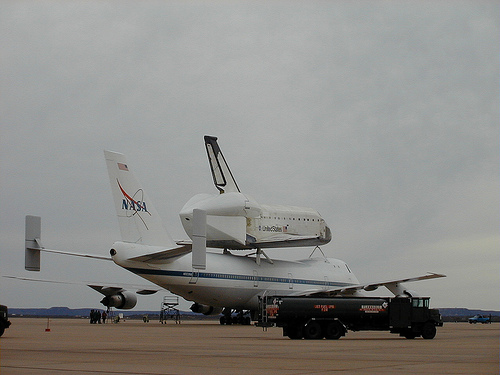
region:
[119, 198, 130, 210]
blue letter on plane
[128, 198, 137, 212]
blue letter on plane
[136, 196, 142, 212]
blue letter on plane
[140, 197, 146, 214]
blue letter on plane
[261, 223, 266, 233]
blue letter on plane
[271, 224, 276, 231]
blue letter on plane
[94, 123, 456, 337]
this is a plane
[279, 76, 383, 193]
the sky is cloudy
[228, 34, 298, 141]
the sky is cloudy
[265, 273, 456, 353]
this is a luggage vehicle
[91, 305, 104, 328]
this is a person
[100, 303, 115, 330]
this is a person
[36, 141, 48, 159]
a cloud in the sky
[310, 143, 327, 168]
a cloud in the sky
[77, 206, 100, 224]
a cloud in the sky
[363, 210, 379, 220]
a cloud in the sky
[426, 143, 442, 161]
a cloud in the sky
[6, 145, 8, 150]
a cloud in the sky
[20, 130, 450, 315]
an airplane with a shuttle on top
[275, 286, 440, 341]
a long black truck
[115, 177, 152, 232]
a nasa symbol on a plane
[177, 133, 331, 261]
a shuttle with a tall black wing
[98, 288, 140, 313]
a turbine for a plane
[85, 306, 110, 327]
people standing on concrete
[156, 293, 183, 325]
a staircase for boarding planes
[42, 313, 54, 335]
an orange safety marker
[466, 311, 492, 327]
a blue truck in the distance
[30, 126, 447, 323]
shuttle riding piggyback on airplane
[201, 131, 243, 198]
black and white rectangle on tail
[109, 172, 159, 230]
logo of aeronautics organization on tail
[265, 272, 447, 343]
black truck close to plane wing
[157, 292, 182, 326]
platform and railing under plane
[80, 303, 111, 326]
people standing under wing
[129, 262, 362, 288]
dark stripe along length of plane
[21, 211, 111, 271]
horizontal pole with rectangle at end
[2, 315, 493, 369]
flat brown surface of airfield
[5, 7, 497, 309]
huge bright sky over planes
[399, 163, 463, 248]
Section of the sky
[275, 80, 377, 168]
Section of the sky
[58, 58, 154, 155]
Section of the sky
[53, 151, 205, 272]
Section of the sky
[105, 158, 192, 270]
the tail of an airplane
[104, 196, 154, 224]
the logo of an airplane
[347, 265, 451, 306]
the wing of an airplane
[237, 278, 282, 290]
the windows of an airplane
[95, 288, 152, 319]
the turbine of an airplane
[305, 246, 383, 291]
the front of an airplane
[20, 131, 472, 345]
A plane on a runway.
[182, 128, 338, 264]
A plane on top of another plane.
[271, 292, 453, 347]
A black fuel truck.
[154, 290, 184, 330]
A metal rolling ladder.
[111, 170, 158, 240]
Nasa logo on the tail of the plane.